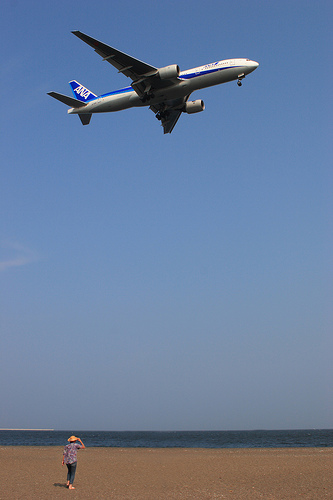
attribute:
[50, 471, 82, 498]
feet — bare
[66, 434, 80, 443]
hat — beige